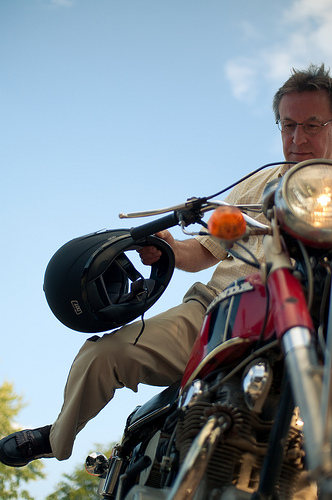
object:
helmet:
[43, 227, 176, 334]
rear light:
[83, 451, 110, 479]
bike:
[84, 158, 332, 500]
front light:
[275, 158, 332, 243]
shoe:
[0, 423, 55, 469]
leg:
[0, 280, 214, 469]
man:
[0, 64, 332, 469]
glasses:
[276, 116, 332, 135]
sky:
[0, 1, 331, 500]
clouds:
[290, 0, 332, 56]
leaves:
[0, 383, 15, 408]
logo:
[71, 301, 82, 316]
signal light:
[206, 204, 246, 242]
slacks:
[49, 281, 222, 461]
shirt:
[197, 163, 296, 296]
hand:
[136, 226, 174, 266]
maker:
[205, 280, 254, 314]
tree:
[46, 443, 121, 500]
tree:
[0, 380, 48, 500]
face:
[279, 96, 327, 163]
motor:
[179, 372, 246, 490]